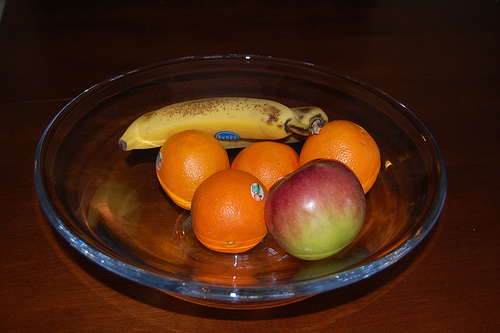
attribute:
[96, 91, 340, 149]
banana — ripe, yellow, brown dotted, black bottomed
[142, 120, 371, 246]
oranges — four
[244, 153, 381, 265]
apple — red, green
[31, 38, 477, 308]
plate — round, clear, large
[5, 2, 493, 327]
surface — brown, wooden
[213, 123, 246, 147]
sticker — blue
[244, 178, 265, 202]
sticker — white